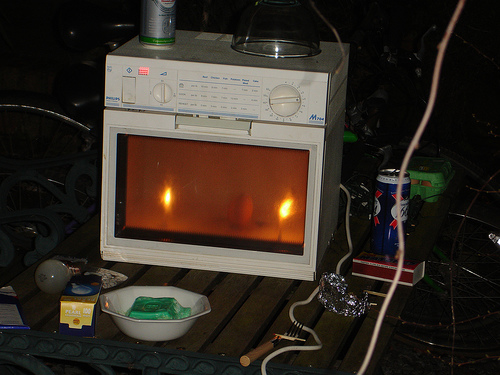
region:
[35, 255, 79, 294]
incandescent light bulb on left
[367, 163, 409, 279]
blue and white drink can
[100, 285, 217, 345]
white bowl with green stuff inside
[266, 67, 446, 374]
power cord to appliance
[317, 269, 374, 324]
crumpled foil-like silver ball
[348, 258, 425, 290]
red and white box of matches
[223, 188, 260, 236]
brown egg in appliance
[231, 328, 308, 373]
tool laying on counter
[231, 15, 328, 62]
glass bowl on top of appliance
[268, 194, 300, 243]
candle flame in appliance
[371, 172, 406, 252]
Beer can sitting on wood slat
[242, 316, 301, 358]
Silver fork with wooden handle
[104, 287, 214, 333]
White bowl on wooden slats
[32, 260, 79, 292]
Glass light bulb on wooden slats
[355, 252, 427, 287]
Red and white box of matches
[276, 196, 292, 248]
Lit candle behind glass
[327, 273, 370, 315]
Ball of aluminum foil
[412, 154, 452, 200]
Green box beside beer can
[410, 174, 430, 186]
Brown eggs inside box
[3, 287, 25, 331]
Blue and white piece of paper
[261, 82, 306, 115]
The knob of a microwave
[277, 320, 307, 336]
The top portion of a fork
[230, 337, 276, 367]
The bottom portion of a fork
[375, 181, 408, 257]
The bottom portion of a soda can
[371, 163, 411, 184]
The top portion of a soda can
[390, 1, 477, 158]
The upper portion of a cable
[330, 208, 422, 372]
The bottom portion of a cable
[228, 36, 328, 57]
The bottom portion of a glass vase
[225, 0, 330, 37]
The top portion of a glass vase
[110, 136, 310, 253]
The inside portion of a microwave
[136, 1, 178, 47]
a can of beer on a mirowave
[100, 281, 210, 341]
a white bowl on a wooden table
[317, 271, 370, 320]
a crumple sheet of aluminum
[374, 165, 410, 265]
a can of beer on top of a box of matches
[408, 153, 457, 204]
a 6 eggs green container on a table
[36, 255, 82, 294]
a lightbulb on a table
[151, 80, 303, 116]
white dials on a microwave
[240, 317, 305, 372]
a fork with a wooden handle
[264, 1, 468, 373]
a white wire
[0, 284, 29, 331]
a blue wrapper on a table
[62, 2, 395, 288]
the microwave oven is on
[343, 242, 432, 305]
a box of matches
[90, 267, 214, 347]
a bowl on the table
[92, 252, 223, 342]
the bowl is white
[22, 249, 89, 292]
a light bulb on the table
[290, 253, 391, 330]
a piece of foil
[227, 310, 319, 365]
a fork on the table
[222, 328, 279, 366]
the handle is made of wood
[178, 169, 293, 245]
an egg in the microwave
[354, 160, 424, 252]
a can on the table